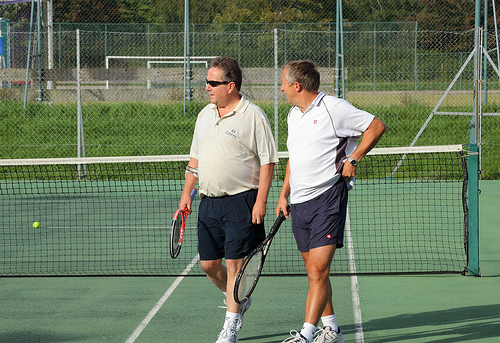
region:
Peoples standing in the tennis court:
[170, 52, 370, 336]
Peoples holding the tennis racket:
[168, 204, 281, 303]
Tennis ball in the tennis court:
[28, 219, 47, 235]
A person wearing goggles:
[203, 76, 217, 88]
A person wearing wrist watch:
[348, 153, 363, 168]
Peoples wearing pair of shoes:
[219, 288, 347, 341]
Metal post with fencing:
[12, 28, 163, 113]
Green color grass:
[41, 105, 148, 140]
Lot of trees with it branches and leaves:
[226, 0, 442, 22]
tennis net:
[37, 161, 146, 259]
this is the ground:
[92, 284, 129, 310]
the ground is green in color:
[59, 301, 94, 337]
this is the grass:
[121, 105, 163, 152]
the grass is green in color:
[126, 98, 153, 143]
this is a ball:
[28, 213, 42, 230]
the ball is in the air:
[25, 211, 55, 236]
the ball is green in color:
[28, 219, 38, 227]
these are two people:
[160, 58, 385, 320]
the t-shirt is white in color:
[302, 163, 315, 174]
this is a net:
[398, 174, 464, 237]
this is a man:
[281, 65, 360, 233]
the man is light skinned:
[357, 130, 381, 148]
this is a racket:
[231, 225, 286, 297]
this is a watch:
[337, 158, 366, 171]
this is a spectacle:
[196, 73, 225, 95]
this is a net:
[396, 164, 455, 264]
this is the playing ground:
[89, 292, 183, 329]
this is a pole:
[174, 4, 194, 81]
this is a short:
[312, 200, 340, 249]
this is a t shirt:
[301, 121, 326, 188]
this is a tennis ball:
[25, 216, 47, 235]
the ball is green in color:
[22, 217, 43, 229]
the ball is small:
[25, 215, 46, 233]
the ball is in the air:
[13, 220, 53, 235]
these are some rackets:
[162, 192, 305, 314]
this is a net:
[87, 167, 147, 257]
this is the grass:
[95, 105, 120, 130]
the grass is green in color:
[100, 127, 119, 141]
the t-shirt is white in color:
[291, 137, 308, 166]